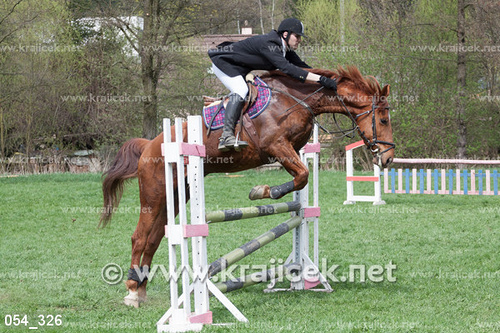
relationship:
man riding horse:
[207, 15, 340, 155] [96, 64, 397, 312]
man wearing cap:
[207, 15, 340, 155] [276, 16, 305, 51]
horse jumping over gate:
[96, 64, 397, 312] [153, 114, 333, 331]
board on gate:
[178, 140, 207, 159] [153, 114, 333, 331]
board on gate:
[185, 222, 211, 239] [153, 114, 333, 331]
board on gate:
[303, 207, 320, 220] [153, 114, 333, 331]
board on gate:
[300, 144, 322, 154] [153, 114, 333, 331]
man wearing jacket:
[207, 15, 340, 155] [208, 33, 312, 86]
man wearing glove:
[207, 15, 340, 155] [317, 74, 336, 93]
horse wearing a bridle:
[96, 64, 397, 312] [363, 96, 398, 161]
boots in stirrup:
[216, 92, 251, 153] [232, 120, 242, 155]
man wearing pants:
[207, 15, 340, 155] [208, 62, 248, 96]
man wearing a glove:
[207, 15, 340, 155] [317, 74, 336, 93]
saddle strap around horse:
[237, 117, 270, 163] [96, 64, 397, 312]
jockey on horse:
[207, 15, 340, 155] [96, 64, 397, 312]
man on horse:
[207, 15, 340, 155] [96, 64, 397, 312]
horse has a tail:
[96, 64, 397, 312] [99, 135, 152, 232]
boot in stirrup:
[216, 92, 251, 153] [232, 120, 242, 155]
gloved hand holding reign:
[317, 74, 336, 93] [332, 96, 375, 149]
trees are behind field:
[4, 1, 499, 161] [0, 166, 499, 331]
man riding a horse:
[207, 15, 340, 155] [96, 64, 397, 312]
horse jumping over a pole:
[96, 64, 397, 312] [203, 202, 299, 224]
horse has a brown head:
[96, 64, 397, 312] [335, 60, 397, 173]